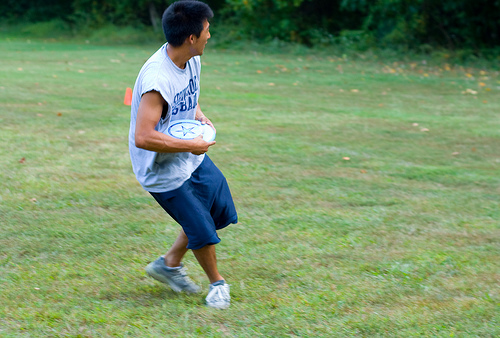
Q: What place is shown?
A: It is a park.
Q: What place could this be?
A: It is a park.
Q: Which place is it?
A: It is a park.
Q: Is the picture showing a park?
A: Yes, it is showing a park.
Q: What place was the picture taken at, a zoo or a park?
A: It was taken at a park.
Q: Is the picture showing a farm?
A: No, the picture is showing a park.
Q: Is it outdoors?
A: Yes, it is outdoors.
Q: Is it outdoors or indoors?
A: It is outdoors.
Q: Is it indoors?
A: No, it is outdoors.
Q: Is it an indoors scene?
A: No, it is outdoors.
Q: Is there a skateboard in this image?
A: No, there are no skateboards.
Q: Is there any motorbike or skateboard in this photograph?
A: No, there are no skateboards or motorcycles.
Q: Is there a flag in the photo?
A: Yes, there is a flag.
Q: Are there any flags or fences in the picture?
A: Yes, there is a flag.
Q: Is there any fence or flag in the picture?
A: Yes, there is a flag.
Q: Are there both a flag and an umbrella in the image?
A: No, there is a flag but no umbrellas.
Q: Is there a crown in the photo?
A: No, there are no crowns.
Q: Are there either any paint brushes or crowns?
A: No, there are no crowns or paint brushes.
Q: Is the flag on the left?
A: Yes, the flag is on the left of the image.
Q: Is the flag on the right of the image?
A: No, the flag is on the left of the image.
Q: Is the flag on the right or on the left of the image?
A: The flag is on the left of the image.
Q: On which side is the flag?
A: The flag is on the left of the image.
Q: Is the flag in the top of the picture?
A: Yes, the flag is in the top of the image.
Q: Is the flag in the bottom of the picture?
A: No, the flag is in the top of the image.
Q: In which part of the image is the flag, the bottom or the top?
A: The flag is in the top of the image.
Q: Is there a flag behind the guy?
A: Yes, there is a flag behind the guy.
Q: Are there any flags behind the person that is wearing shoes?
A: Yes, there is a flag behind the guy.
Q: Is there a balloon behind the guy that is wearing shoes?
A: No, there is a flag behind the guy.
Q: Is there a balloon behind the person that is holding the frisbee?
A: No, there is a flag behind the guy.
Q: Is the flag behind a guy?
A: Yes, the flag is behind a guy.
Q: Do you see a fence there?
A: No, there are no fences.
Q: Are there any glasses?
A: No, there are no glasses.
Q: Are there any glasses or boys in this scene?
A: No, there are no glasses or boys.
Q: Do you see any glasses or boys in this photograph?
A: No, there are no glasses or boys.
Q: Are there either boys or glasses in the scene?
A: No, there are no glasses or boys.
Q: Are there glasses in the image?
A: No, there are no glasses.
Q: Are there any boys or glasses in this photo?
A: No, there are no glasses or boys.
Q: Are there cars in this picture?
A: No, there are no cars.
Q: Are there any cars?
A: No, there are no cars.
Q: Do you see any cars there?
A: No, there are no cars.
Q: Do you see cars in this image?
A: No, there are no cars.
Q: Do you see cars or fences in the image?
A: No, there are no cars or fences.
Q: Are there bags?
A: No, there are no bags.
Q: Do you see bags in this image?
A: No, there are no bags.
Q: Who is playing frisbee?
A: The guy is playing frisbee.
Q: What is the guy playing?
A: The guy is playing frisbee.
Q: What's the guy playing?
A: The guy is playing frisbee.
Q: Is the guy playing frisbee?
A: Yes, the guy is playing frisbee.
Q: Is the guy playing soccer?
A: No, the guy is playing frisbee.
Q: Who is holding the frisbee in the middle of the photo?
A: The guy is holding the frisbee.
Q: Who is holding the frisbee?
A: The guy is holding the frisbee.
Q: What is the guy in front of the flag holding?
A: The guy is holding the frisbee.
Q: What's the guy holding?
A: The guy is holding the frisbee.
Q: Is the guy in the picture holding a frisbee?
A: Yes, the guy is holding a frisbee.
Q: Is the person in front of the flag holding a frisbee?
A: Yes, the guy is holding a frisbee.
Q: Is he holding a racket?
A: No, the guy is holding a frisbee.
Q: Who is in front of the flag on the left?
A: The guy is in front of the flag.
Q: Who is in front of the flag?
A: The guy is in front of the flag.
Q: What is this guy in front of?
A: The guy is in front of the flag.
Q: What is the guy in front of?
A: The guy is in front of the flag.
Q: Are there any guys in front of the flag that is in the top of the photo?
A: Yes, there is a guy in front of the flag.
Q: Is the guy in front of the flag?
A: Yes, the guy is in front of the flag.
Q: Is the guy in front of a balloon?
A: No, the guy is in front of the flag.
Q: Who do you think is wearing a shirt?
A: The guy is wearing a shirt.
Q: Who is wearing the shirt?
A: The guy is wearing a shirt.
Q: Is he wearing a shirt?
A: Yes, the guy is wearing a shirt.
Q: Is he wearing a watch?
A: No, the guy is wearing a shirt.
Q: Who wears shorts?
A: The guy wears shorts.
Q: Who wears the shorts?
A: The guy wears shorts.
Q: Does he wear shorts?
A: Yes, the guy wears shorts.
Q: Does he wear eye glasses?
A: No, the guy wears shorts.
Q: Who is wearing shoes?
A: The guy is wearing shoes.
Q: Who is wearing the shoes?
A: The guy is wearing shoes.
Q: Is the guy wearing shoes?
A: Yes, the guy is wearing shoes.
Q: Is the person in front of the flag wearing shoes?
A: Yes, the guy is wearing shoes.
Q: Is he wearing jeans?
A: No, the guy is wearing shoes.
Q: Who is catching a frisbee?
A: The guy is catching a frisbee.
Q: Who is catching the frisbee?
A: The guy is catching a frisbee.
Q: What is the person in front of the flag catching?
A: The guy is catching a frisbee.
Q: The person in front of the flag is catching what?
A: The guy is catching a frisbee.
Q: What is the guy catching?
A: The guy is catching a frisbee.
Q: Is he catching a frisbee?
A: Yes, the guy is catching a frisbee.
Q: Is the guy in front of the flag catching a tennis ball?
A: No, the guy is catching a frisbee.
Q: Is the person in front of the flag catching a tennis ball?
A: No, the guy is catching a frisbee.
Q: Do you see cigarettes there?
A: No, there are no cigarettes.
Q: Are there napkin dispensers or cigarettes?
A: No, there are no cigarettes or napkin dispensers.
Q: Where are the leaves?
A: The leaves are on the ground.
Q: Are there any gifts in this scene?
A: No, there are no gifts.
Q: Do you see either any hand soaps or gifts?
A: No, there are no gifts or hand soaps.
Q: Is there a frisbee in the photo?
A: Yes, there is a frisbee.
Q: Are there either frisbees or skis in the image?
A: Yes, there is a frisbee.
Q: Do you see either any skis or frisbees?
A: Yes, there is a frisbee.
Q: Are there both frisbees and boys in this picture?
A: No, there is a frisbee but no boys.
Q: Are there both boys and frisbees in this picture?
A: No, there is a frisbee but no boys.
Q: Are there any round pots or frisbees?
A: Yes, there is a round frisbee.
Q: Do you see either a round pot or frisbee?
A: Yes, there is a round frisbee.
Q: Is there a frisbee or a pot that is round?
A: Yes, the frisbee is round.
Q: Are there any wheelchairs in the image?
A: No, there are no wheelchairs.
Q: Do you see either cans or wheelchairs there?
A: No, there are no wheelchairs or cans.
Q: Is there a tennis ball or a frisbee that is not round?
A: No, there is a frisbee but it is round.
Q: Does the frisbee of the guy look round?
A: Yes, the frisbee is round.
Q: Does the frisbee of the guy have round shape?
A: Yes, the frisbee is round.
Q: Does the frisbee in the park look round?
A: Yes, the frisbee is round.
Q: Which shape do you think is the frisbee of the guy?
A: The frisbee is round.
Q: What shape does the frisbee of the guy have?
A: The frisbee has round shape.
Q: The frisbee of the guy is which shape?
A: The frisbee is round.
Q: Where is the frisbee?
A: The frisbee is in the park.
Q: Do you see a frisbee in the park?
A: Yes, there is a frisbee in the park.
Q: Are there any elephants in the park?
A: No, there is a frisbee in the park.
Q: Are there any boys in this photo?
A: No, there are no boys.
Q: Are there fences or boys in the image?
A: No, there are no boys or fences.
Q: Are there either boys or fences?
A: No, there are no boys or fences.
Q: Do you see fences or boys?
A: No, there are no boys or fences.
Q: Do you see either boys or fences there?
A: No, there are no boys or fences.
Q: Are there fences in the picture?
A: No, there are no fences.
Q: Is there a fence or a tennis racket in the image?
A: No, there are no fences or rackets.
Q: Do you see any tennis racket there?
A: No, there are no rackets.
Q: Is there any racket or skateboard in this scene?
A: No, there are no rackets or skateboards.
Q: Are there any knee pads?
A: No, there are no knee pads.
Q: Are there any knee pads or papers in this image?
A: No, there are no knee pads or papers.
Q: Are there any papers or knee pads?
A: No, there are no knee pads or papers.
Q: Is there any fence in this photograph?
A: No, there are no fences.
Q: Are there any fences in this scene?
A: No, there are no fences.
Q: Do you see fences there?
A: No, there are no fences.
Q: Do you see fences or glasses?
A: No, there are no fences or glasses.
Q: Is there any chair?
A: No, there are no chairs.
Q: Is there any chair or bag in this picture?
A: No, there are no chairs or bags.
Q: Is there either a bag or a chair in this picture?
A: No, there are no chairs or bags.